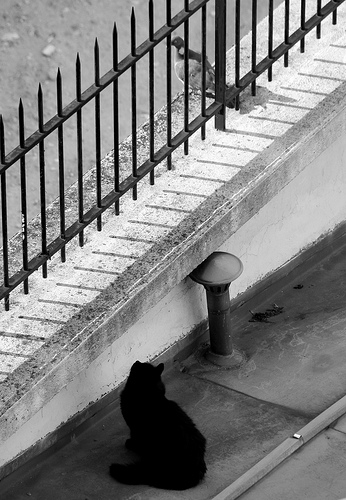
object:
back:
[137, 388, 208, 490]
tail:
[109, 462, 147, 484]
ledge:
[0, 0, 286, 250]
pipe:
[189, 251, 244, 356]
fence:
[0, 0, 346, 313]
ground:
[0, 0, 346, 420]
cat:
[108, 360, 208, 492]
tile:
[204, 282, 234, 356]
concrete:
[0, 222, 346, 500]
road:
[232, 410, 346, 499]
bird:
[171, 36, 236, 109]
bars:
[251, 0, 256, 96]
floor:
[0, 223, 346, 499]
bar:
[214, 0, 226, 131]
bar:
[184, 0, 189, 155]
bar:
[130, 6, 137, 200]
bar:
[94, 37, 102, 232]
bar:
[18, 97, 28, 295]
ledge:
[0, 81, 346, 416]